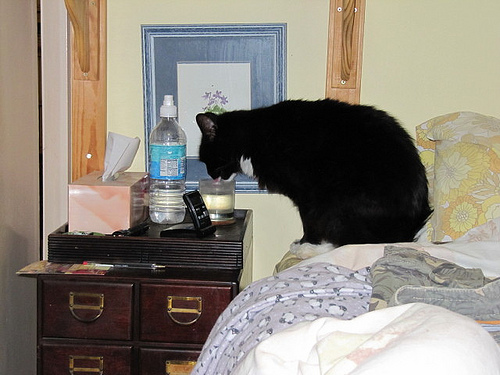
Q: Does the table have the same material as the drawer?
A: Yes, both the table and the drawer are made of wood.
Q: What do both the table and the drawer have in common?
A: The material, both the table and the drawer are wooden.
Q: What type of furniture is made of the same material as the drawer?
A: The table is made of the same material as the drawer.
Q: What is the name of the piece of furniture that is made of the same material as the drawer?
A: The piece of furniture is a table.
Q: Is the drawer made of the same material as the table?
A: Yes, both the drawer and the table are made of wood.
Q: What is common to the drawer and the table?
A: The material, both the drawer and the table are wooden.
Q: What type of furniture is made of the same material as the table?
A: The drawer is made of the same material as the table.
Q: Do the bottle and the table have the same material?
A: No, the bottle is made of plastic and the table is made of wood.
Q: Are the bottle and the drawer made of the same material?
A: No, the bottle is made of plastic and the drawer is made of wood.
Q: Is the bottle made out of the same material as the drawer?
A: No, the bottle is made of plastic and the drawer is made of wood.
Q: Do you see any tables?
A: Yes, there is a table.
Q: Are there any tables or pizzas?
A: Yes, there is a table.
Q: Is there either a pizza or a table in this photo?
A: Yes, there is a table.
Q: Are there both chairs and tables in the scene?
A: No, there is a table but no chairs.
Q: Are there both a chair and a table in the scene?
A: No, there is a table but no chairs.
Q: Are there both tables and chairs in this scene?
A: No, there is a table but no chairs.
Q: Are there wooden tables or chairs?
A: Yes, there is a wood table.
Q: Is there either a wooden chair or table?
A: Yes, there is a wood table.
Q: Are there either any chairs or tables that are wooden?
A: Yes, the table is wooden.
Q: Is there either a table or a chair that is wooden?
A: Yes, the table is wooden.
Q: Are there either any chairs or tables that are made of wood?
A: Yes, the table is made of wood.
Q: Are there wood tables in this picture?
A: Yes, there is a wood table.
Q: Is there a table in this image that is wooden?
A: Yes, there is a table that is wooden.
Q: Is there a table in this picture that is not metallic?
A: Yes, there is a wooden table.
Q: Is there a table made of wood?
A: Yes, there is a table that is made of wood.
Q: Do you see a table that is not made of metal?
A: Yes, there is a table that is made of wood.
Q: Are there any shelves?
A: No, there are no shelves.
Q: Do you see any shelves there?
A: No, there are no shelves.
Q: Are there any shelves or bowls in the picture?
A: No, there are no shelves or bowls.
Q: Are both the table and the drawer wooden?
A: Yes, both the table and the drawer are wooden.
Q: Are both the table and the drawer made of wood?
A: Yes, both the table and the drawer are made of wood.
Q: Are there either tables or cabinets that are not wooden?
A: No, there is a table but it is wooden.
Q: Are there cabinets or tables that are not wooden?
A: No, there is a table but it is wooden.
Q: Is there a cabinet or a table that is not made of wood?
A: No, there is a table but it is made of wood.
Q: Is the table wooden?
A: Yes, the table is wooden.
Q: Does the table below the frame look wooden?
A: Yes, the table is wooden.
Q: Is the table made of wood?
A: Yes, the table is made of wood.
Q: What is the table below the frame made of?
A: The table is made of wood.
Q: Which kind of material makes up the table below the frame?
A: The table is made of wood.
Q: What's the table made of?
A: The table is made of wood.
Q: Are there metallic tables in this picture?
A: No, there is a table but it is wooden.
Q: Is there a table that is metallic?
A: No, there is a table but it is wooden.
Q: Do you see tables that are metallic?
A: No, there is a table but it is wooden.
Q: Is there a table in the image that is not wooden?
A: No, there is a table but it is wooden.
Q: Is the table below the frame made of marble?
A: No, the table is made of wood.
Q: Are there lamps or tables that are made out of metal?
A: No, there is a table but it is made of wood.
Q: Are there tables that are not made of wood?
A: No, there is a table but it is made of wood.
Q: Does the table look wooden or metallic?
A: The table is wooden.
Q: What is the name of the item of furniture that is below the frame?
A: The piece of furniture is a table.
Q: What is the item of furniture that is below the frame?
A: The piece of furniture is a table.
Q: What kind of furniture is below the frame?
A: The piece of furniture is a table.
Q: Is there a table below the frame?
A: Yes, there is a table below the frame.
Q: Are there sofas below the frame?
A: No, there is a table below the frame.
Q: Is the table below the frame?
A: Yes, the table is below the frame.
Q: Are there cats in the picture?
A: Yes, there is a cat.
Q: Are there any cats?
A: Yes, there is a cat.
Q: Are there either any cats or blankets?
A: Yes, there is a cat.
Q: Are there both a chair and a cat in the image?
A: No, there is a cat but no chairs.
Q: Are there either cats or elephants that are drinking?
A: Yes, the cat is drinking.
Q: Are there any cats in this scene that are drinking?
A: Yes, there is a cat that is drinking.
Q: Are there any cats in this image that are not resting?
A: Yes, there is a cat that is drinking.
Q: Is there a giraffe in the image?
A: No, there are no giraffes.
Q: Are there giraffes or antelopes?
A: No, there are no giraffes or antelopes.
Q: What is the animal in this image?
A: The animal is a cat.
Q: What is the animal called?
A: The animal is a cat.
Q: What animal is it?
A: The animal is a cat.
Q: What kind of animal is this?
A: That is a cat.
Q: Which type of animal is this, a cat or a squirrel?
A: That is a cat.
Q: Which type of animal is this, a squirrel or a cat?
A: That is a cat.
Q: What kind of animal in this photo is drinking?
A: The animal is a cat.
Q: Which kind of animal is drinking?
A: The animal is a cat.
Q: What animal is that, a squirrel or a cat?
A: That is a cat.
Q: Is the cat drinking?
A: Yes, the cat is drinking.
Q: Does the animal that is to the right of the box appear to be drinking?
A: Yes, the cat is drinking.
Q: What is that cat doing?
A: The cat is drinking.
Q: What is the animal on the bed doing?
A: The cat is drinking.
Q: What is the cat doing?
A: The cat is drinking.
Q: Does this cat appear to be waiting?
A: No, the cat is drinking.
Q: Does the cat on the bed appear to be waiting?
A: No, the cat is drinking.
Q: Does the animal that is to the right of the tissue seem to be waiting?
A: No, the cat is drinking.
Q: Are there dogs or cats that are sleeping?
A: No, there is a cat but it is drinking.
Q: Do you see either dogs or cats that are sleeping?
A: No, there is a cat but it is drinking.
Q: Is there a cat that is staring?
A: No, there is a cat but it is drinking.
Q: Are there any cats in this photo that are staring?
A: No, there is a cat but it is drinking.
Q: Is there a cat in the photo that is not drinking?
A: No, there is a cat but it is drinking.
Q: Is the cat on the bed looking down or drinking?
A: The cat is drinking.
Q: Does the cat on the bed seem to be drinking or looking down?
A: The cat is drinking.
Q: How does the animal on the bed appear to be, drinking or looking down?
A: The cat is drinking.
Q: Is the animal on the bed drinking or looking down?
A: The cat is drinking.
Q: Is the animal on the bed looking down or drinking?
A: The cat is drinking.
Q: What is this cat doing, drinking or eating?
A: The cat is drinking.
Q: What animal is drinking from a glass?
A: The cat is drinking from a glass.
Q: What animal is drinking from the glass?
A: The cat is drinking from a glass.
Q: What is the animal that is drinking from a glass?
A: The animal is a cat.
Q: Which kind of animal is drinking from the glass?
A: The animal is a cat.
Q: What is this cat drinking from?
A: The cat is drinking from a glass.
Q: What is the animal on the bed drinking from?
A: The cat is drinking from a glass.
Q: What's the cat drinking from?
A: The cat is drinking from a glass.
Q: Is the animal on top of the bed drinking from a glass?
A: Yes, the cat is drinking from a glass.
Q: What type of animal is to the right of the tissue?
A: The animal is a cat.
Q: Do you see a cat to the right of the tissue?
A: Yes, there is a cat to the right of the tissue.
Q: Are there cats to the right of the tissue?
A: Yes, there is a cat to the right of the tissue.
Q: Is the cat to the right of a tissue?
A: Yes, the cat is to the right of a tissue.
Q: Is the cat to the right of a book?
A: No, the cat is to the right of a tissue.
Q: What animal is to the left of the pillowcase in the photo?
A: The animal is a cat.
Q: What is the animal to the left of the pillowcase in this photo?
A: The animal is a cat.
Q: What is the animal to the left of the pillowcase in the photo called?
A: The animal is a cat.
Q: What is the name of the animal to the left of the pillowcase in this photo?
A: The animal is a cat.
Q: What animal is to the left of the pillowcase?
A: The animal is a cat.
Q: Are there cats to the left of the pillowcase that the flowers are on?
A: Yes, there is a cat to the left of the pillow case.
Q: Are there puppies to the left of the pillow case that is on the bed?
A: No, there is a cat to the left of the pillowcase.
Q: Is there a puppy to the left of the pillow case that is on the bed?
A: No, there is a cat to the left of the pillowcase.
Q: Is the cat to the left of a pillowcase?
A: Yes, the cat is to the left of a pillowcase.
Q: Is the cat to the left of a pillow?
A: No, the cat is to the left of a pillowcase.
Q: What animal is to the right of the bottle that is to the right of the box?
A: The animal is a cat.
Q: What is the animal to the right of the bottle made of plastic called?
A: The animal is a cat.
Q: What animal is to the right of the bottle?
A: The animal is a cat.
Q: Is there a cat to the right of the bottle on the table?
A: Yes, there is a cat to the right of the bottle.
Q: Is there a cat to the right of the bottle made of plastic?
A: Yes, there is a cat to the right of the bottle.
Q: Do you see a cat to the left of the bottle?
A: No, the cat is to the right of the bottle.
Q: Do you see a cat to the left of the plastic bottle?
A: No, the cat is to the right of the bottle.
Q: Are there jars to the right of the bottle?
A: No, there is a cat to the right of the bottle.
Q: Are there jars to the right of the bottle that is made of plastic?
A: No, there is a cat to the right of the bottle.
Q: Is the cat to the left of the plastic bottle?
A: No, the cat is to the right of the bottle.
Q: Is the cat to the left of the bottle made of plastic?
A: No, the cat is to the right of the bottle.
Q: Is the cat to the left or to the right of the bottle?
A: The cat is to the right of the bottle.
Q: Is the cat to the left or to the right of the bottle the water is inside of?
A: The cat is to the right of the bottle.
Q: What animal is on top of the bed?
A: The cat is on top of the bed.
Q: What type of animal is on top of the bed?
A: The animal is a cat.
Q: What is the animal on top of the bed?
A: The animal is a cat.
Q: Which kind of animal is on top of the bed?
A: The animal is a cat.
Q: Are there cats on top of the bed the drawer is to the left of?
A: Yes, there is a cat on top of the bed.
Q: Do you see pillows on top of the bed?
A: No, there is a cat on top of the bed.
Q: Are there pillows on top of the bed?
A: No, there is a cat on top of the bed.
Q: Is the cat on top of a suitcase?
A: No, the cat is on top of a bed.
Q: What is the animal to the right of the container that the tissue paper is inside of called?
A: The animal is a cat.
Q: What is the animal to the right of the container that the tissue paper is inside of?
A: The animal is a cat.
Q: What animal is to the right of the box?
A: The animal is a cat.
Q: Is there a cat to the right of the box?
A: Yes, there is a cat to the right of the box.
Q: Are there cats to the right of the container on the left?
A: Yes, there is a cat to the right of the box.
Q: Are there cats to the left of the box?
A: No, the cat is to the right of the box.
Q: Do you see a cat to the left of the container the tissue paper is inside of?
A: No, the cat is to the right of the box.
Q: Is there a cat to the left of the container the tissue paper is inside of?
A: No, the cat is to the right of the box.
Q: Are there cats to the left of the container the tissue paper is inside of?
A: No, the cat is to the right of the box.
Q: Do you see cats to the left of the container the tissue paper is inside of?
A: No, the cat is to the right of the box.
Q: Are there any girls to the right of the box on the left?
A: No, there is a cat to the right of the box.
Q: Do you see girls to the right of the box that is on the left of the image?
A: No, there is a cat to the right of the box.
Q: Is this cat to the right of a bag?
A: No, the cat is to the right of the box.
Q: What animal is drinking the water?
A: The cat is drinking the water.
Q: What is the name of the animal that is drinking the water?
A: The animal is a cat.